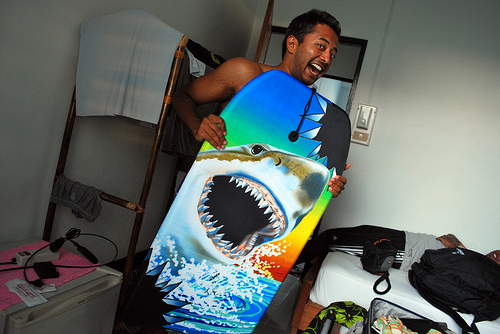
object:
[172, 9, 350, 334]
man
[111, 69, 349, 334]
surfboard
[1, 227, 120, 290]
cord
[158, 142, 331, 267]
shark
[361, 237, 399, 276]
camera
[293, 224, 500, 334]
person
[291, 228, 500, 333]
bed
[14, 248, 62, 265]
power strip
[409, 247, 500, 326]
backpack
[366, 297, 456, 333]
suitcase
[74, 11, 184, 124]
towel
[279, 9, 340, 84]
head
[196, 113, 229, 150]
hand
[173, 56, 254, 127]
arm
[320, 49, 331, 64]
nose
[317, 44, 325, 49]
eye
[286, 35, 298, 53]
ear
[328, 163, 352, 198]
hand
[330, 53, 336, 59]
eye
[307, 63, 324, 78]
mouth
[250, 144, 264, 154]
eye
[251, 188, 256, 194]
tooth